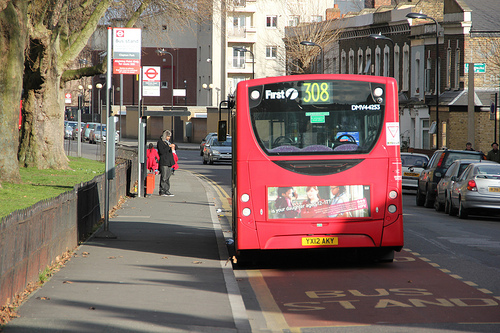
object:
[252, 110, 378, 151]
windshield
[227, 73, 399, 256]
bus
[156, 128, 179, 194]
man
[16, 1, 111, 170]
tree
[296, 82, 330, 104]
numbers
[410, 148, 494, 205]
car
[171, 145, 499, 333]
street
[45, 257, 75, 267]
leaves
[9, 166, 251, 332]
sidewalk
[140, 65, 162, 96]
sign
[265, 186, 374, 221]
banner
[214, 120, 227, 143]
rear view mirror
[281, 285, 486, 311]
painting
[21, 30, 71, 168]
large tree trunk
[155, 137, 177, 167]
coat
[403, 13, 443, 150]
street lamp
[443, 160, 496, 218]
cars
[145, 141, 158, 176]
woman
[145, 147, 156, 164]
red jacket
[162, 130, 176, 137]
hat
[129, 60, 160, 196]
bus stop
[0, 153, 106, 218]
grass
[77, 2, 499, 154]
building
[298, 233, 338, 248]
license plate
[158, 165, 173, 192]
jeans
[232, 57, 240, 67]
windows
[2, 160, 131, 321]
wall